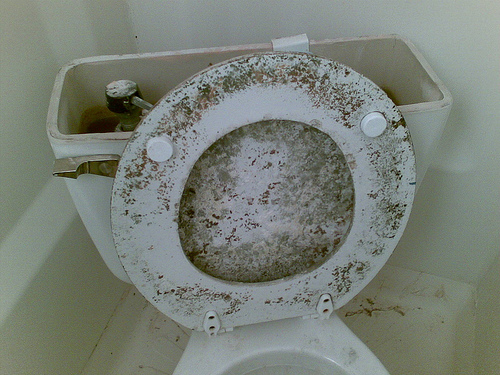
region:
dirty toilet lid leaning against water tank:
[107, 47, 417, 322]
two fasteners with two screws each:
[196, 290, 336, 335]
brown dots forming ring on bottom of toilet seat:
[110, 46, 420, 331]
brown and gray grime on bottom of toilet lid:
[175, 111, 355, 286]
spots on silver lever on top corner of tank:
[45, 147, 115, 183]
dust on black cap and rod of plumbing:
[101, 75, 151, 112]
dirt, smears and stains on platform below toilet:
[85, 255, 480, 370]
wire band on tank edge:
[265, 30, 310, 50]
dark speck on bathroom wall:
[5, 0, 485, 171]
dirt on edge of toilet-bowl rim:
[175, 325, 385, 370]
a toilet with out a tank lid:
[112, 25, 418, 326]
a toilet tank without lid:
[41, 28, 473, 360]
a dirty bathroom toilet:
[36, 13, 443, 373]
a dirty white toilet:
[94, 48, 465, 343]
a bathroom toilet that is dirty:
[79, 44, 491, 348]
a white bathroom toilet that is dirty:
[100, 36, 467, 311]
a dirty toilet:
[40, 41, 459, 370]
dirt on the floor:
[377, 285, 464, 343]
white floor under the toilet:
[100, 321, 168, 358]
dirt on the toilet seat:
[180, 72, 346, 109]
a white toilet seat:
[98, 55, 403, 323]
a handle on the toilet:
[54, 150, 112, 175]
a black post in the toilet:
[106, 74, 158, 124]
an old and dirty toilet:
[40, 36, 458, 373]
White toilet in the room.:
[45, 28, 461, 372]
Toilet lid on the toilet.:
[108, 50, 430, 343]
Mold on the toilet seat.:
[106, 43, 423, 343]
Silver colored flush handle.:
[47, 150, 120, 186]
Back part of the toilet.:
[46, 38, 458, 278]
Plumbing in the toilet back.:
[100, 70, 163, 130]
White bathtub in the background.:
[2, 8, 133, 369]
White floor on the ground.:
[81, 228, 489, 370]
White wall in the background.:
[128, 2, 493, 292]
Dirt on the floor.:
[340, 287, 422, 332]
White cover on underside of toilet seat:
[360, 112, 385, 138]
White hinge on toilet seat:
[200, 314, 222, 337]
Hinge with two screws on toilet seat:
[317, 290, 333, 320]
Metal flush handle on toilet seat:
[49, 157, 126, 180]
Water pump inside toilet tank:
[104, 82, 155, 133]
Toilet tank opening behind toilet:
[50, 49, 452, 134]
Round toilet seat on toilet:
[105, 53, 420, 311]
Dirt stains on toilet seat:
[337, 261, 370, 288]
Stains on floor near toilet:
[345, 305, 412, 321]